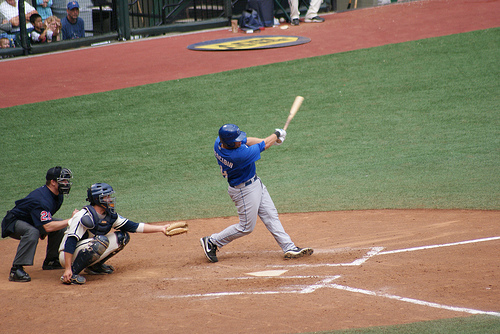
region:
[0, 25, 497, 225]
green grass on baseball field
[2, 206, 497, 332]
dirt on the baseball field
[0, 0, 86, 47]
people watching baseball game from the stands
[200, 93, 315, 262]
baseball player batting a baseball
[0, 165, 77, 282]
baseball umpire wearing a black shirt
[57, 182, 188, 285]
baseball catcher wearing a black and white uniform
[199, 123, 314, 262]
baseball batter wearing a blue and grey uniform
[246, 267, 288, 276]
home plate on the baseball field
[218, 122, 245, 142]
batter's blue safety helmet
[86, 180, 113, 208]
catcher's black safety helmet and mask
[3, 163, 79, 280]
baseball umpire dressed in black shirt and grey pants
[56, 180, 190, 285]
baseball catcher in white and black uniform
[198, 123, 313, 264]
baseball batter in blue and grey uniform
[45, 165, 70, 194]
umpire's black safety helmet and mask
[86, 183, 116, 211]
baseball catcher's black safety helmet and mask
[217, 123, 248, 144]
baseball batter's blue safety helmet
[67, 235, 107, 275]
baseball player's black shin guard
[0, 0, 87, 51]
people sitting in the stands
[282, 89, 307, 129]
a brown baseball bat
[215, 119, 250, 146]
a blue helmet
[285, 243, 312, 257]
the shoe of a man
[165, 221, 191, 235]
a brown baseball glove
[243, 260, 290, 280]
a white base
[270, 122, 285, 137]
a white glove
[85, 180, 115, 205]
a blue baseball helmet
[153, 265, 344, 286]
a long white line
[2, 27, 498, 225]
a section of green grass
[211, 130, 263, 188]
a man's blue shirt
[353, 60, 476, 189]
The grass is short and green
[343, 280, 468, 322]
The line on the ground is white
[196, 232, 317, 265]
The feet of the man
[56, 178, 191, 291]
The catcher of the baseball game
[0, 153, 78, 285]
The umpire is bending over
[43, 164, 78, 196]
The umpire has on a face guard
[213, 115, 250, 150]
The man has on a helmet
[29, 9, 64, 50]
A kid in the stands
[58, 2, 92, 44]
The man sitting in the stands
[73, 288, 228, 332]
The dirt on the field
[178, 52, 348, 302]
this is a man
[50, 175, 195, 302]
this is a man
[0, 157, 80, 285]
this is a man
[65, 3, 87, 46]
this is a man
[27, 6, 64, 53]
this is a man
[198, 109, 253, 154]
the man is wearing a helmet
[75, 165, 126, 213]
the man is wearing a helmet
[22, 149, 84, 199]
the man is wearing a helmet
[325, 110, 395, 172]
this is a patch of grass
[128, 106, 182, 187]
this is a patch of grass